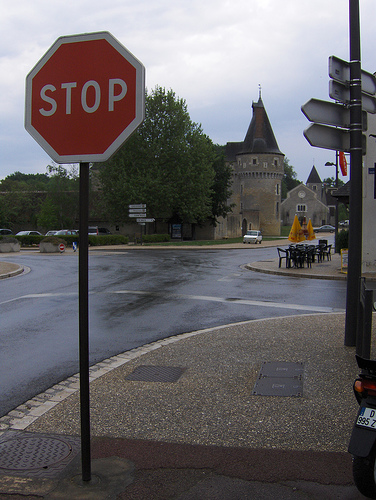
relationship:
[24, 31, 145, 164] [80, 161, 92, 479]
sign on pole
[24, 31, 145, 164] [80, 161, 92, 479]
sign placed on pole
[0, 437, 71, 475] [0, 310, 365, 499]
manhole on sidewalk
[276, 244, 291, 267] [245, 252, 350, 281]
chair on sidewalk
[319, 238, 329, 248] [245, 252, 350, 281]
chair on sidewalk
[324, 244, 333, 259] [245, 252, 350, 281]
chair on sidewalk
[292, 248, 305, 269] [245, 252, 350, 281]
chair on sidewalk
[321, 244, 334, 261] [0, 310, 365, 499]
chair on sidewalk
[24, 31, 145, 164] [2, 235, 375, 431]
sign beside street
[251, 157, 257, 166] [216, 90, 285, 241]
window on building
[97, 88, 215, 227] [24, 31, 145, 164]
tree behind sign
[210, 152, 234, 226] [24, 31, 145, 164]
tree behind sign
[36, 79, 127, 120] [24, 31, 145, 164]
writing on sign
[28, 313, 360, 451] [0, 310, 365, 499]
gravel on sidewalk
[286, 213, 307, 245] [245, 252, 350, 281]
umbrella on sidewalk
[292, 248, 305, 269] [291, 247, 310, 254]
chair around table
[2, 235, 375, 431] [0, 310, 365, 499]
street beside sidewalk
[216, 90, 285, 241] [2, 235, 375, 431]
building across street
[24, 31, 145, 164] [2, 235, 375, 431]
sign for street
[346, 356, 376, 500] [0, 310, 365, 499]
motorcycle on sidewalk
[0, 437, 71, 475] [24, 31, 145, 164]
manhole beside sign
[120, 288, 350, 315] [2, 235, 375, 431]
line in street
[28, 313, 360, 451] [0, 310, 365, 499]
gravel makes up sidewalk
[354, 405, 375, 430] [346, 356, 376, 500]
license on bike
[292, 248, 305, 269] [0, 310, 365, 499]
chair on sidewalk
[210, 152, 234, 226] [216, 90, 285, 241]
tree in front of building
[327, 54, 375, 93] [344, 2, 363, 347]
sign on pole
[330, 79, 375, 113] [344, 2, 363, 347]
sign on pole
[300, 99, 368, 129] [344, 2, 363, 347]
sign on pole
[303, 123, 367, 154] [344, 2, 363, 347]
sign on pole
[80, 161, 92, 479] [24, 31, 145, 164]
pole attached to sign